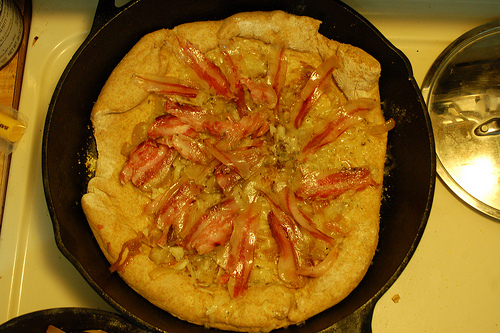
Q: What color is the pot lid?
A: Silver.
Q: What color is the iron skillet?
A: Black.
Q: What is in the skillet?
A: A pizza.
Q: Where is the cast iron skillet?
A: On the stove.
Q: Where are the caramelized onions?
A: On top of the bread.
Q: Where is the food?
A: Pan.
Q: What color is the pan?
A: Black.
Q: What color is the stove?
A: White.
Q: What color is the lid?
A: Silver.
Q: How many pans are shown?
A: One.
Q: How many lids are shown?
A: One.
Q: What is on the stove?
A: A pan.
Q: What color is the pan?
A: Black.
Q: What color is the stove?
A: White.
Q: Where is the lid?
A: To the right of the pan.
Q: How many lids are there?
A: One.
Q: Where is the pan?
A: On the stove.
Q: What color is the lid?
A: Silver.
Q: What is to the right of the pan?
A: A lid.